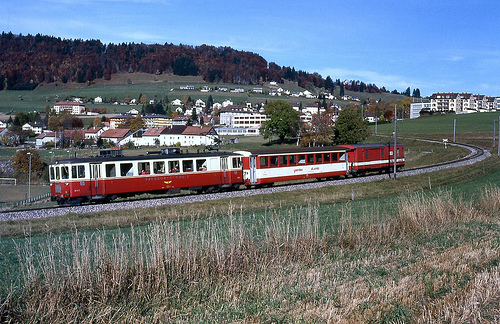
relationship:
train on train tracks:
[47, 143, 404, 206] [0, 133, 498, 232]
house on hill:
[123, 118, 223, 139] [381, 111, 498, 144]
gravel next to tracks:
[24, 203, 203, 222] [0, 134, 499, 241]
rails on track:
[443, 125, 478, 179] [0, 128, 496, 229]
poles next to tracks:
[14, 142, 55, 214] [6, 128, 497, 234]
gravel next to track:
[24, 203, 203, 222] [0, 128, 496, 229]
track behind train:
[413, 125, 462, 189] [51, 139, 423, 205]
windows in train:
[55, 156, 225, 174] [48, 135, 410, 211]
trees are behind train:
[25, 34, 268, 76] [45, 126, 415, 206]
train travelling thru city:
[47, 143, 404, 206] [0, 89, 489, 178]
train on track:
[47, 143, 404, 206] [0, 123, 483, 245]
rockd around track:
[92, 212, 492, 320] [0, 131, 500, 239]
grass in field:
[83, 227, 442, 312] [6, 116, 497, 321]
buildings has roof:
[424, 75, 499, 119] [416, 87, 493, 103]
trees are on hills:
[25, 34, 268, 76] [0, 69, 363, 112]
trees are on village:
[25, 34, 268, 76] [1, 60, 401, 157]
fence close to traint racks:
[5, 197, 50, 207] [0, 121, 490, 245]